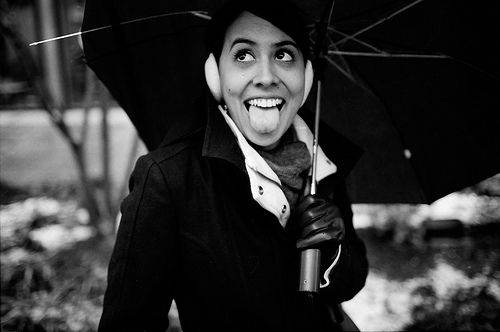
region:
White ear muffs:
[195, 48, 227, 110]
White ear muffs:
[304, 60, 326, 113]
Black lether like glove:
[295, 180, 358, 270]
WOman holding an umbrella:
[32, 2, 495, 322]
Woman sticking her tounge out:
[130, 8, 363, 179]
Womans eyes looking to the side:
[222, 25, 307, 73]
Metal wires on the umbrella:
[351, 13, 498, 78]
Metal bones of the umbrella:
[334, 13, 464, 83]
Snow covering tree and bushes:
[12, 39, 112, 239]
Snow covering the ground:
[391, 265, 495, 322]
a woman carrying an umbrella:
[30, 2, 487, 329]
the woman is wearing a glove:
[285, 191, 351, 250]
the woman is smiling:
[192, 8, 319, 151]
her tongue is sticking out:
[246, 103, 283, 135]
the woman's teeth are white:
[244, 94, 283, 106]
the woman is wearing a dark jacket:
[87, 119, 371, 329]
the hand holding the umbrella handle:
[295, 183, 345, 295]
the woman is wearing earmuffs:
[200, 7, 314, 122]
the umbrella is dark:
[21, 9, 496, 206]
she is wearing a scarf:
[221, 100, 336, 228]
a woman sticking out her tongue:
[178, 7, 355, 200]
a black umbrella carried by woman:
[76, 2, 498, 221]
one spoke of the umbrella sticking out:
[16, 26, 91, 51]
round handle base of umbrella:
[295, 247, 332, 304]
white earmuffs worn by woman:
[196, 48, 233, 103]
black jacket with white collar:
[78, 108, 417, 330]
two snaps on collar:
[252, 181, 307, 236]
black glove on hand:
[292, 186, 359, 269]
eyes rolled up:
[227, 43, 308, 81]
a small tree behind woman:
[6, 20, 149, 237]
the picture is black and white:
[3, 1, 488, 323]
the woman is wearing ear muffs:
[185, 38, 320, 100]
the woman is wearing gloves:
[264, 188, 357, 263]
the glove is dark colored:
[277, 180, 354, 292]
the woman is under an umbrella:
[74, 1, 406, 316]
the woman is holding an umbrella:
[64, 4, 392, 313]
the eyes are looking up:
[212, 35, 299, 68]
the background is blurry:
[14, 88, 121, 311]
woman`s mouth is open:
[227, 88, 291, 137]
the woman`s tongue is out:
[228, 97, 298, 144]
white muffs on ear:
[204, 51, 226, 101]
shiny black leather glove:
[294, 194, 345, 253]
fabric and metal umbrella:
[80, 3, 499, 200]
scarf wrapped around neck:
[256, 140, 314, 200]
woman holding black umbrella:
[79, 3, 446, 330]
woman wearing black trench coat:
[106, 9, 371, 329]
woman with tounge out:
[115, 5, 352, 330]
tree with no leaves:
[13, 21, 120, 232]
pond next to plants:
[356, 224, 497, 330]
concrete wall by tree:
[3, 112, 146, 202]